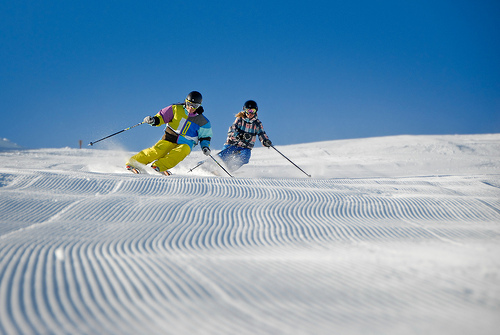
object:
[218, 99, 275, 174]
person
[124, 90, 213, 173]
person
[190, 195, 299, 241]
lines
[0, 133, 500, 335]
snow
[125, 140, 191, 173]
snow pants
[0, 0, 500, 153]
sky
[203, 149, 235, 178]
pole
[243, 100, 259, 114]
hat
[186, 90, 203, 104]
hat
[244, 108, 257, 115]
goggles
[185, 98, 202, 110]
goggles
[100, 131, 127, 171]
spray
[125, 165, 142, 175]
skis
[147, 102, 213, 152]
jacket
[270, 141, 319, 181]
pole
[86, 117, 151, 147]
pole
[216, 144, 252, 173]
pants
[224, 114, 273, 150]
jacket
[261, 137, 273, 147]
glove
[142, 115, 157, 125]
glove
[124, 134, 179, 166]
legs